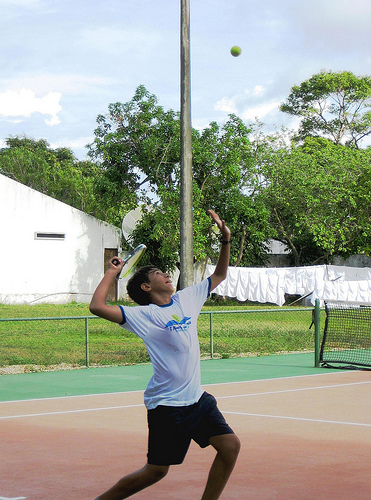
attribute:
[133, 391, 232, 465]
shorts — blue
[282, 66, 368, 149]
tree — large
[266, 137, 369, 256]
tree — large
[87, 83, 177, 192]
tree — large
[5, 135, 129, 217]
tree — large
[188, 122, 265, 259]
tree — large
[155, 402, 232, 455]
shorts — black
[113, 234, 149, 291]
racket — green, white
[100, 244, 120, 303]
door — wooden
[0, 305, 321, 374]
fence — metal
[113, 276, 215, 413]
shirt — white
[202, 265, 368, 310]
clothes — white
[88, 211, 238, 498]
man — young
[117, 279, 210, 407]
shirt — white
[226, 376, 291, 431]
line — long, white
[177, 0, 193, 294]
pole — electrical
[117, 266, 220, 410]
shirt — short sleeve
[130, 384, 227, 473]
shorts — dark